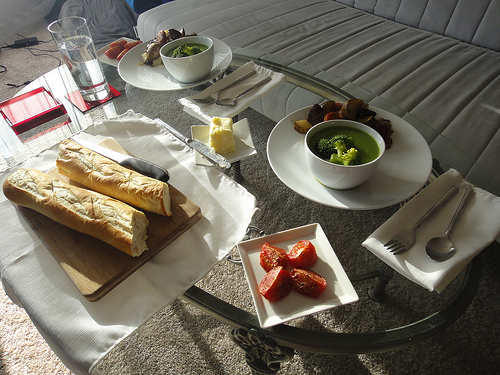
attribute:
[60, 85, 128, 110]
coaster — red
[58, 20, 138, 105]
cup — clear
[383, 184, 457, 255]
fork — silver 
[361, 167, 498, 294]
napkin — white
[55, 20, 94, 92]
glass — tall 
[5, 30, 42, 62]
cord — black, computer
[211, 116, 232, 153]
butter — yellow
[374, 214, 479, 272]
setting — shoddy 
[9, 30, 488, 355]
table — glass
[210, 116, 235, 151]
butter — one inch, piece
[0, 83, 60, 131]
coaster holder — pictured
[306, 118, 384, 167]
soup — broccoli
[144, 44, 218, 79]
bowl — white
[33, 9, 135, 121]
glass — pictured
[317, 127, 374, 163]
brocolli — green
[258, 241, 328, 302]
tomatoes —  grilled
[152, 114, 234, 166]
butterknife — used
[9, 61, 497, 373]
carpet — Light 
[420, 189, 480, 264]
spoon — silver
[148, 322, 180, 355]
carpet — light brown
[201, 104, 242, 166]
butter — yellow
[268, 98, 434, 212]
plate — white 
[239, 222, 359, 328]
plate —  white,  square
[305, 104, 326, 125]
vegetable — roasted , seasoned 